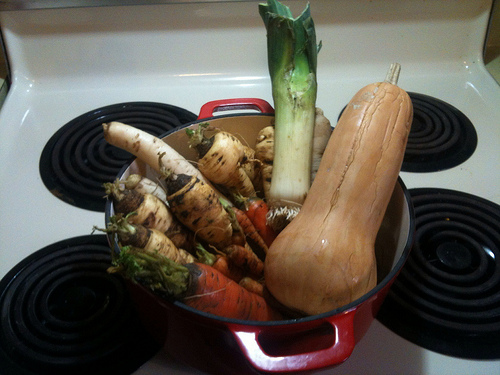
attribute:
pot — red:
[107, 96, 416, 374]